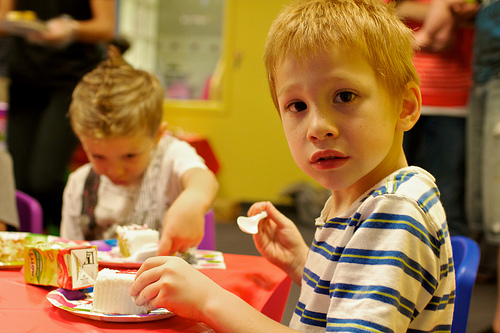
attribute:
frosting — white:
[95, 268, 138, 284]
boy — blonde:
[240, 7, 461, 323]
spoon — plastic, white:
[228, 205, 276, 236]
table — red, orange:
[5, 238, 289, 326]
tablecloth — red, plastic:
[200, 246, 294, 316]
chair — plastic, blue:
[448, 228, 484, 332]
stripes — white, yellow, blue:
[340, 239, 446, 286]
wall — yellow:
[221, 13, 280, 197]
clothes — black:
[10, 7, 79, 161]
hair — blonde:
[266, 11, 411, 72]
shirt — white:
[60, 145, 200, 231]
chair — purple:
[197, 212, 224, 251]